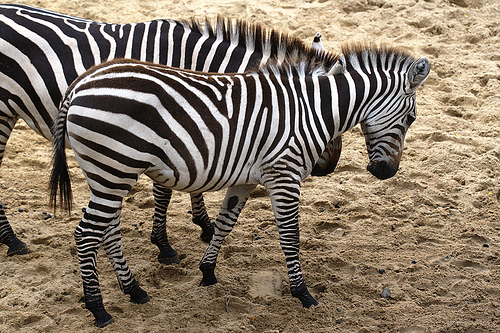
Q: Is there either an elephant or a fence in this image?
A: No, there are no fences or elephants.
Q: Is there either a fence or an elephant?
A: No, there are no fences or elephants.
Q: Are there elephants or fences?
A: No, there are no fences or elephants.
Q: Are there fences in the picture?
A: No, there are no fences.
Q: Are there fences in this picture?
A: No, there are no fences.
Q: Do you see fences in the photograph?
A: No, there are no fences.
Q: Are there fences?
A: No, there are no fences.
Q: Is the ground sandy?
A: Yes, the ground is sandy.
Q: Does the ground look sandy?
A: Yes, the ground is sandy.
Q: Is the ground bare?
A: No, the ground is sandy.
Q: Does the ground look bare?
A: No, the ground is sandy.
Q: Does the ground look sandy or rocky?
A: The ground is sandy.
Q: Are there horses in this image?
A: No, there are no horses.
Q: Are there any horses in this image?
A: No, there are no horses.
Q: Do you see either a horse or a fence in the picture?
A: No, there are no horses or fences.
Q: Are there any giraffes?
A: No, there are no giraffes.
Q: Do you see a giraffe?
A: No, there are no giraffes.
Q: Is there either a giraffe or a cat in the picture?
A: No, there are no giraffes or cats.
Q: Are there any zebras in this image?
A: Yes, there is a zebra.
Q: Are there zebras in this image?
A: Yes, there is a zebra.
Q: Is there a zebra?
A: Yes, there is a zebra.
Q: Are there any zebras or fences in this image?
A: Yes, there is a zebra.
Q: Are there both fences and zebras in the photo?
A: No, there is a zebra but no fences.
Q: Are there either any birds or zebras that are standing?
A: Yes, the zebra is standing.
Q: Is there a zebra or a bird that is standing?
A: Yes, the zebra is standing.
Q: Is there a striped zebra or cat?
A: Yes, there is a striped zebra.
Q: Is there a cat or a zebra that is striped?
A: Yes, the zebra is striped.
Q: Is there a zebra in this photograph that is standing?
A: Yes, there is a zebra that is standing.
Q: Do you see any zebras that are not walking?
A: Yes, there is a zebra that is standing .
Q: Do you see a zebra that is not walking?
A: Yes, there is a zebra that is standing .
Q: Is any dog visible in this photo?
A: No, there are no dogs.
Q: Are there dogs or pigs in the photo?
A: No, there are no dogs or pigs.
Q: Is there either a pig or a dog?
A: No, there are no dogs or pigs.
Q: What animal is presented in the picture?
A: The animal is a zebra.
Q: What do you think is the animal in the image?
A: The animal is a zebra.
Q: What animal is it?
A: The animal is a zebra.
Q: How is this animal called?
A: This is a zebra.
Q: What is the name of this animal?
A: This is a zebra.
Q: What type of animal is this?
A: This is a zebra.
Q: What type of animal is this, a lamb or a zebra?
A: This is a zebra.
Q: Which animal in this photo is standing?
A: The animal is a zebra.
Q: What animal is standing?
A: The animal is a zebra.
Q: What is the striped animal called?
A: The animal is a zebra.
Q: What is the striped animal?
A: The animal is a zebra.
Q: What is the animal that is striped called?
A: The animal is a zebra.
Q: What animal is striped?
A: The animal is a zebra.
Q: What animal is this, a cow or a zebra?
A: This is a zebra.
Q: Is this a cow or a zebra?
A: This is a zebra.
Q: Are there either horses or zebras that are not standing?
A: No, there is a zebra but it is standing.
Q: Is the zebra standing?
A: Yes, the zebra is standing.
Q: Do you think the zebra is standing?
A: Yes, the zebra is standing.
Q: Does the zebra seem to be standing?
A: Yes, the zebra is standing.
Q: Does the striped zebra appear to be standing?
A: Yes, the zebra is standing.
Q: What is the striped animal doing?
A: The zebra is standing.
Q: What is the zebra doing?
A: The zebra is standing.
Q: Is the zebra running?
A: No, the zebra is standing.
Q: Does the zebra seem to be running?
A: No, the zebra is standing.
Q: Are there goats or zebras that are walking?
A: No, there is a zebra but it is standing.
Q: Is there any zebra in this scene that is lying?
A: No, there is a zebra but it is standing.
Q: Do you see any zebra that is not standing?
A: No, there is a zebra but it is standing.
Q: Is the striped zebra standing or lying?
A: The zebra is standing.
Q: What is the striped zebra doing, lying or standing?
A: The zebra is standing.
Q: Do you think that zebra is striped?
A: Yes, the zebra is striped.